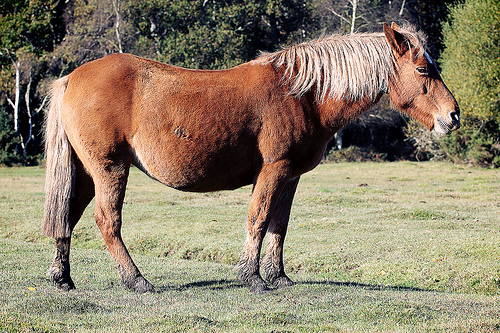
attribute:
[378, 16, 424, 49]
ears — brown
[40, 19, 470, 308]
plant — green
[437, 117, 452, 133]
teeth — sharp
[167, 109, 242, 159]
coat — brown with a gray spot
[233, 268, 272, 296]
horse hoof — black, steady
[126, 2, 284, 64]
shrub — green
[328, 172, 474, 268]
grass — green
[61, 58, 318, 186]
body — brown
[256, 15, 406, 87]
mane — gray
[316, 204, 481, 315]
grass — green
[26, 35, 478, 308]
horse — brown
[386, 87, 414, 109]
jaw muscle — thick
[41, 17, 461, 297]
horse — brown